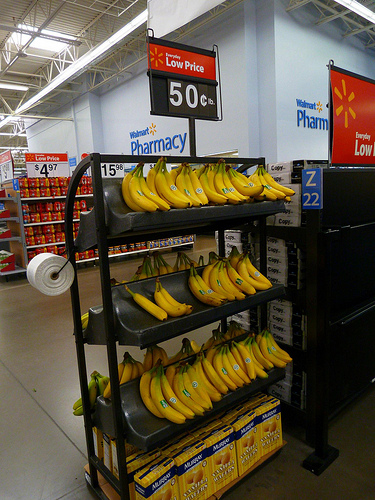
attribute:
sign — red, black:
[144, 31, 224, 123]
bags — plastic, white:
[25, 251, 75, 296]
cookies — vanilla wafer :
[96, 392, 285, 499]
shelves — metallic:
[65, 152, 290, 500]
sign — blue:
[300, 169, 323, 211]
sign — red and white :
[326, 58, 374, 168]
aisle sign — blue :
[301, 167, 323, 210]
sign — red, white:
[25, 151, 70, 178]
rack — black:
[102, 176, 289, 451]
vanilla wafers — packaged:
[91, 394, 284, 499]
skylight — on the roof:
[9, 23, 76, 55]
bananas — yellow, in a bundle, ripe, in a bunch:
[128, 165, 296, 438]